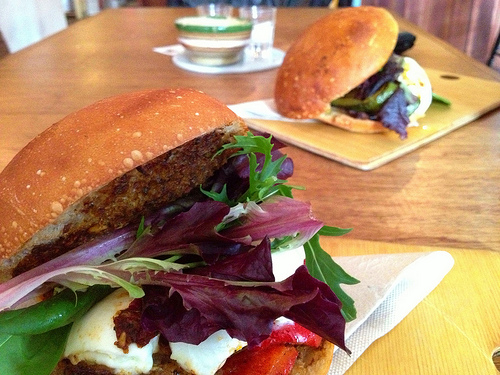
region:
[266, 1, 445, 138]
the bread has lettuce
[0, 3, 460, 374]
the bread is on the table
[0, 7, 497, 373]
long wood dining table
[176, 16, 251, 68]
bowl with green trim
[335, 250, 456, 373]
corner of folded napkin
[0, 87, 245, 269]
top half of hamburger bun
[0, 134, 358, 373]
green and purple lettuce leaves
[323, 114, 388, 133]
bottom edge of hamburger bun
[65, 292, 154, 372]
surface of melted white cheese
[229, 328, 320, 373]
light reflection on red vegetable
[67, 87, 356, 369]
a burger and a salad combined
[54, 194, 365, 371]
a tomato buried by lettuce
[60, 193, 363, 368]
cheese jiblets it appears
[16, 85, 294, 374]
meat that is hiding in a sandwich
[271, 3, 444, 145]
the bun stacked at an angle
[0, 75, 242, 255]
a bun with sparing use of sesame seeds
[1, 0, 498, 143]
two glasses of candles in background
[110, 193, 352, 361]
could be red fire purple lettuce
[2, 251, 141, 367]
a green bean hidden away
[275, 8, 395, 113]
dark spot on bun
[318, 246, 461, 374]
White folded paper towel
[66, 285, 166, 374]
White melting cheese on a burger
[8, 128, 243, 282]
A meat burger patty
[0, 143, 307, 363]
Field greens topping the burger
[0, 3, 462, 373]
Two burgers on a table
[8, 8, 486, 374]
Two burgers on cutting board plates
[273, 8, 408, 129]
A giant bun for the top of the burger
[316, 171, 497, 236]
Wood grain on a table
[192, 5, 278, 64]
Two clear glasses in the background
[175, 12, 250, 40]
A bowl lined with a green rim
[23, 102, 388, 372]
burger on a table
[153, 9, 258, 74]
green and gold bowl on table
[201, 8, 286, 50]
two cups by a bowl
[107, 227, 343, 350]
purple lettuce on burger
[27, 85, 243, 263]
tilted hamburger bun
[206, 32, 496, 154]
hamburger on yellow plate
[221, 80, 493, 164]
the plate is rectangular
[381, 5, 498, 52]
patterned curtain in background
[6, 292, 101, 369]
spinach leaves on burger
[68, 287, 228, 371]
melted cheese on burger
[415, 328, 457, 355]
yellow place mat on table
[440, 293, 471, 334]
tiny grooves in yellow placemat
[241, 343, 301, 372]
juicy piece of red strawberry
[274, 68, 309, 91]
tiny pieces of sesame seed on bun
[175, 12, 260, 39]
white bowl with green trim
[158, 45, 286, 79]
white circular dinner plate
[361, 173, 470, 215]
large brown dining table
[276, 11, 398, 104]
large brown hamburger bun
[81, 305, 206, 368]
gooey American cheese on food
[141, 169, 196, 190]
crispy well done hamburger meat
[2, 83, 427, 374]
Hamburger filled with fixings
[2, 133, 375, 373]
Green and purple lettuce on a burger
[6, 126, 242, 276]
A hamburger patty in a bun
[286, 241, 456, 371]
A white napkin underneath a hamburger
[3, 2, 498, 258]
A light grain wooden table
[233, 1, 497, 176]
A hamburger in the background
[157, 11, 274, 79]
Two bowls in the background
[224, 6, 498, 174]
A giant burger on a wooden plate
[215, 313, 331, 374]
Tomato underneath a hamburger bun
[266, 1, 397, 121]
An oversized top to a hamburger bun